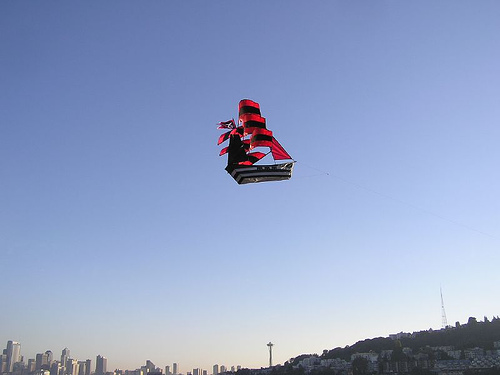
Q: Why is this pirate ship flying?
A: It's a kite.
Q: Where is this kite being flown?
A: In a field.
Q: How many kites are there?
A: One.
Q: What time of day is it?
A: Daytime.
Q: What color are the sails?
A: Red and black.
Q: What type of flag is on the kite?
A: A pirates flag.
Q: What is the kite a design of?
A: A pirates ship.